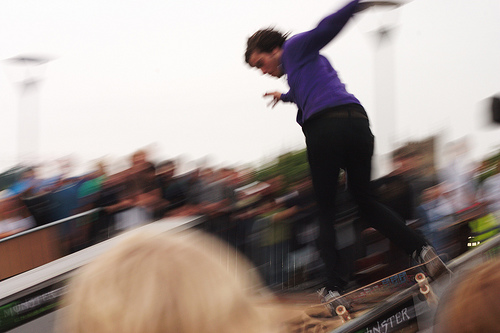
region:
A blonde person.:
[40, 225, 279, 330]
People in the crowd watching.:
[7, 145, 242, 225]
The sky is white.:
[81, 47, 184, 118]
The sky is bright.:
[74, 33, 203, 118]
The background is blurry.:
[19, 137, 261, 214]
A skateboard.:
[302, 246, 478, 326]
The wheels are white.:
[293, 233, 471, 323]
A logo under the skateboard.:
[346, 293, 451, 330]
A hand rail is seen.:
[2, 205, 97, 250]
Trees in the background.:
[256, 145, 306, 181]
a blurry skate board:
[281, 257, 463, 319]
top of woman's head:
[61, 220, 306, 331]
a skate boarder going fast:
[237, 5, 455, 309]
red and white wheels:
[323, 270, 454, 314]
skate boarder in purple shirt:
[239, 2, 434, 124]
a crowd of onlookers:
[5, 132, 252, 217]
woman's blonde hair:
[55, 221, 297, 330]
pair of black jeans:
[278, 105, 445, 268]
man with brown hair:
[243, 30, 312, 76]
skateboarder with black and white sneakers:
[303, 242, 458, 299]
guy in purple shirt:
[225, 21, 419, 255]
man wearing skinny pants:
[218, 6, 418, 275]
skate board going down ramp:
[272, 256, 466, 316]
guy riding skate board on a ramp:
[227, 29, 421, 316]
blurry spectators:
[4, 141, 261, 238]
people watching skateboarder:
[45, 115, 314, 247]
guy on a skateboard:
[203, 26, 445, 304]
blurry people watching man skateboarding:
[392, 121, 499, 235]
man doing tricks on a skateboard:
[180, 23, 460, 324]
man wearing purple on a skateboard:
[231, 31, 400, 332]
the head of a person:
[237, 20, 297, 80]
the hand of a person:
[258, 85, 289, 112]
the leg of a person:
[302, 139, 347, 285]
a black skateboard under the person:
[300, 241, 456, 324]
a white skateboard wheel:
[411, 267, 430, 287]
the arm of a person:
[284, 0, 361, 56]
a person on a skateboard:
[232, 1, 464, 330]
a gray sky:
[1, 1, 499, 186]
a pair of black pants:
[289, 97, 429, 286]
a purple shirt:
[276, 2, 360, 123]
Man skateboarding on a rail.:
[246, 12, 448, 309]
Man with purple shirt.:
[248, 26, 403, 115]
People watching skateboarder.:
[15, 146, 277, 192]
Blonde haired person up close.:
[66, 232, 283, 329]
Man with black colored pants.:
[299, 99, 443, 292]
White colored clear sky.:
[83, 58, 235, 124]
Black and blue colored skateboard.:
[311, 260, 475, 321]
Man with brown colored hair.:
[244, 29, 310, 98]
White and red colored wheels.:
[408, 267, 436, 312]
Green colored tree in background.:
[267, 147, 310, 192]